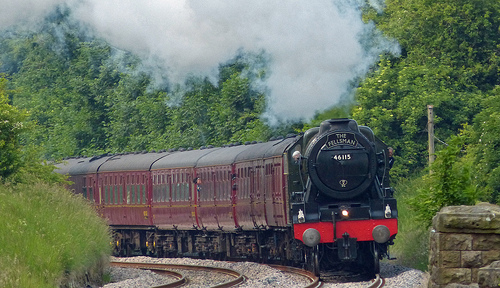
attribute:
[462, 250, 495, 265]
stone — stone 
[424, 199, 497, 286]
wall — stone 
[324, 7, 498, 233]
trees — thick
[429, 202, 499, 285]
wall — stone 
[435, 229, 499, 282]
brick — stone 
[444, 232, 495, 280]
wall — stone, brick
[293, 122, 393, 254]
train — black, red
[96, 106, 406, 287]
train — black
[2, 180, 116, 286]
grass — tall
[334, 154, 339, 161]
number — white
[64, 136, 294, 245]
train cars — burgundy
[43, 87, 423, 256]
train — motion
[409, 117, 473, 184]
pole — wooden 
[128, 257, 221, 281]
train track — curved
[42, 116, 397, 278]
train — has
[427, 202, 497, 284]
stone wall — stone 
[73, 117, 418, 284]
train — red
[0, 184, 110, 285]
grass — green 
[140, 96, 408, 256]
passenger train — long 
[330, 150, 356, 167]
numbers — white